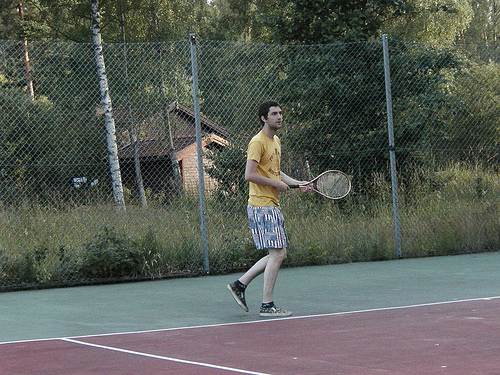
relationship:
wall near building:
[179, 143, 233, 201] [42, 100, 252, 206]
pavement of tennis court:
[3, 247, 498, 342] [2, 294, 497, 372]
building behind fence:
[117, 135, 231, 203] [4, 37, 485, 287]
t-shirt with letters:
[246, 130, 282, 210] [267, 146, 282, 176]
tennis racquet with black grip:
[284, 169, 352, 201] [281, 182, 298, 192]